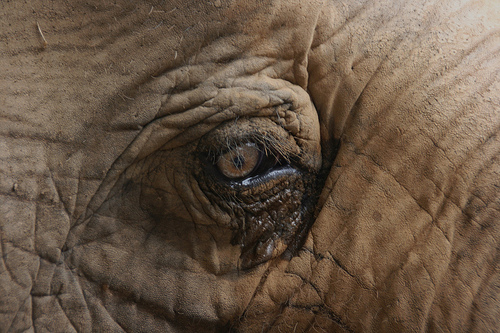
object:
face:
[1, 0, 500, 331]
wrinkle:
[159, 83, 200, 92]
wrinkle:
[215, 80, 278, 91]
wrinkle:
[189, 50, 300, 61]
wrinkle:
[154, 113, 229, 153]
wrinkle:
[304, 0, 324, 89]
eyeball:
[215, 143, 265, 176]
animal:
[2, 0, 499, 333]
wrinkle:
[105, 301, 243, 331]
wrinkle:
[393, 118, 457, 172]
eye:
[199, 135, 299, 187]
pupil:
[233, 155, 244, 168]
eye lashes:
[220, 136, 298, 162]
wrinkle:
[329, 78, 359, 176]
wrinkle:
[309, 250, 352, 290]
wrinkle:
[45, 215, 125, 297]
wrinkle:
[401, 236, 478, 309]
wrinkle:
[64, 136, 118, 237]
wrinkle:
[0, 0, 121, 55]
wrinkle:
[0, 286, 69, 332]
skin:
[4, 0, 500, 332]